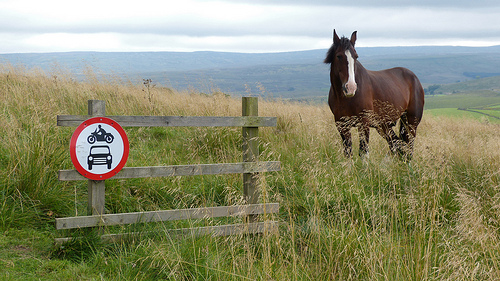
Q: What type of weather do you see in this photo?
A: It is cloudy.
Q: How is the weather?
A: It is cloudy.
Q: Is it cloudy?
A: Yes, it is cloudy.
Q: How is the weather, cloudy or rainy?
A: It is cloudy.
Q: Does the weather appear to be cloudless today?
A: No, it is cloudy.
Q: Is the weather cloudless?
A: No, it is cloudy.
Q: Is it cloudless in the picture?
A: No, it is cloudy.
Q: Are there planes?
A: No, there are no planes.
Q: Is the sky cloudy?
A: Yes, the sky is cloudy.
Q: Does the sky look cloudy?
A: Yes, the sky is cloudy.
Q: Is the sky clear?
A: No, the sky is cloudy.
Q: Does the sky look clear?
A: No, the sky is cloudy.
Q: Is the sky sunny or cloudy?
A: The sky is cloudy.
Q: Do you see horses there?
A: Yes, there is a horse.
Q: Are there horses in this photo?
A: Yes, there is a horse.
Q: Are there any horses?
A: Yes, there is a horse.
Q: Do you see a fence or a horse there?
A: Yes, there is a horse.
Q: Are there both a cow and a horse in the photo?
A: No, there is a horse but no cows.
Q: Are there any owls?
A: No, there are no owls.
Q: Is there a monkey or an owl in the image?
A: No, there are no owls or monkeys.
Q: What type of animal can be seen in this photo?
A: The animal is a horse.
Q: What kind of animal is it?
A: The animal is a horse.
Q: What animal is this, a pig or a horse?
A: This is a horse.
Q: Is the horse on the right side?
A: Yes, the horse is on the right of the image.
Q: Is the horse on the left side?
A: No, the horse is on the right of the image.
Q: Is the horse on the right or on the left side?
A: The horse is on the right of the image.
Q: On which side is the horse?
A: The horse is on the right of the image.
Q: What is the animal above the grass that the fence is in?
A: The animal is a horse.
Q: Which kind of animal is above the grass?
A: The animal is a horse.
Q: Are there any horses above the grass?
A: Yes, there is a horse above the grass.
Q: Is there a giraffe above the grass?
A: No, there is a horse above the grass.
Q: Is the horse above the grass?
A: Yes, the horse is above the grass.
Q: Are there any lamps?
A: No, there are no lamps.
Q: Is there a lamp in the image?
A: No, there are no lamps.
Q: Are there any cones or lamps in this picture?
A: No, there are no lamps or cones.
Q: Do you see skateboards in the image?
A: No, there are no skateboards.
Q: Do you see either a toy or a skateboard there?
A: No, there are no skateboards or toys.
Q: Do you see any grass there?
A: Yes, there is grass.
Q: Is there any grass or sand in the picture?
A: Yes, there is grass.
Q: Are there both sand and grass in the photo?
A: No, there is grass but no sand.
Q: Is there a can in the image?
A: No, there are no cans.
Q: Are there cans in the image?
A: No, there are no cans.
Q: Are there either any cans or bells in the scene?
A: No, there are no cans or bells.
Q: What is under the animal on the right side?
A: The grass is under the horse.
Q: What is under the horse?
A: The grass is under the horse.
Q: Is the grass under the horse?
A: Yes, the grass is under the horse.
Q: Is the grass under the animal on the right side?
A: Yes, the grass is under the horse.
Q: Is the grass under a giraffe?
A: No, the grass is under the horse.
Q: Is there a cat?
A: No, there are no cats.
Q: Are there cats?
A: No, there are no cats.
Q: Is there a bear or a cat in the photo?
A: No, there are no cats or bears.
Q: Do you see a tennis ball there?
A: No, there are no tennis balls.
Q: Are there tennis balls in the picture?
A: No, there are no tennis balls.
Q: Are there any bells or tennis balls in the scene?
A: No, there are no tennis balls or bells.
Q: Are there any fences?
A: Yes, there is a fence.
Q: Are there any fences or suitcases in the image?
A: Yes, there is a fence.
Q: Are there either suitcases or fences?
A: Yes, there is a fence.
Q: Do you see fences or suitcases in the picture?
A: Yes, there is a fence.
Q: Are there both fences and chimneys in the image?
A: No, there is a fence but no chimneys.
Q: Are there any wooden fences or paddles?
A: Yes, there is a wood fence.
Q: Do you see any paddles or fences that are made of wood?
A: Yes, the fence is made of wood.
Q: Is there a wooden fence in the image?
A: Yes, there is a wood fence.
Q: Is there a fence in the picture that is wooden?
A: Yes, there is a fence that is wooden.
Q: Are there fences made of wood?
A: Yes, there is a fence that is made of wood.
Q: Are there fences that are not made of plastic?
A: Yes, there is a fence that is made of wood.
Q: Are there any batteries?
A: No, there are no batteries.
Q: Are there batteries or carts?
A: No, there are no batteries or carts.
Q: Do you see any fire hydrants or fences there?
A: Yes, there is a fence.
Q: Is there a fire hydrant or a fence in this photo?
A: Yes, there is a fence.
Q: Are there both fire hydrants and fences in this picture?
A: No, there is a fence but no fire hydrants.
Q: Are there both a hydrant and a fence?
A: No, there is a fence but no fire hydrants.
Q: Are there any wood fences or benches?
A: Yes, there is a wood fence.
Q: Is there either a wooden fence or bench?
A: Yes, there is a wood fence.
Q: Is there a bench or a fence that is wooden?
A: Yes, the fence is wooden.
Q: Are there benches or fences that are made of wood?
A: Yes, the fence is made of wood.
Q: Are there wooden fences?
A: Yes, there is a wood fence.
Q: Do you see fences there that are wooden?
A: Yes, there is a fence that is wooden.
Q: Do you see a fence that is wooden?
A: Yes, there is a fence that is wooden.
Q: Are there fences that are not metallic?
A: Yes, there is a wooden fence.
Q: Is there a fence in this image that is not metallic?
A: Yes, there is a wooden fence.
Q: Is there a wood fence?
A: Yes, there is a fence that is made of wood.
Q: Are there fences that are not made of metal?
A: Yes, there is a fence that is made of wood.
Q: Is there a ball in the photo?
A: No, there are no balls.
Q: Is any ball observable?
A: No, there are no balls.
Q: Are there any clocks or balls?
A: No, there are no balls or clocks.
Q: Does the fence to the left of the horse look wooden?
A: Yes, the fence is wooden.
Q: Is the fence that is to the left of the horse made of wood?
A: Yes, the fence is made of wood.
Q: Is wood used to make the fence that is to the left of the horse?
A: Yes, the fence is made of wood.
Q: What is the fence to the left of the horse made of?
A: The fence is made of wood.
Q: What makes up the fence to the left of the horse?
A: The fence is made of wood.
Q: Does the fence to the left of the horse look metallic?
A: No, the fence is wooden.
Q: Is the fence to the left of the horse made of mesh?
A: No, the fence is made of wood.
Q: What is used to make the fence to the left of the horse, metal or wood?
A: The fence is made of wood.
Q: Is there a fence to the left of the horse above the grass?
A: Yes, there is a fence to the left of the horse.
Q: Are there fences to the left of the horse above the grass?
A: Yes, there is a fence to the left of the horse.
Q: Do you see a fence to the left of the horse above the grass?
A: Yes, there is a fence to the left of the horse.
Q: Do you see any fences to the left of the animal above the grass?
A: Yes, there is a fence to the left of the horse.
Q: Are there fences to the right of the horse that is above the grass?
A: No, the fence is to the left of the horse.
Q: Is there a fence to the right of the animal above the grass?
A: No, the fence is to the left of the horse.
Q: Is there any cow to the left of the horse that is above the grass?
A: No, there is a fence to the left of the horse.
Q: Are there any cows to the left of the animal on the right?
A: No, there is a fence to the left of the horse.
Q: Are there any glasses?
A: No, there are no glasses.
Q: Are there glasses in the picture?
A: No, there are no glasses.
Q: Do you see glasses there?
A: No, there are no glasses.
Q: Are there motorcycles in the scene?
A: Yes, there is a motorcycle.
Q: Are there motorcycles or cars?
A: Yes, there is a motorcycle.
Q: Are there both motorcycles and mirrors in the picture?
A: No, there is a motorcycle but no mirrors.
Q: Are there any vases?
A: No, there are no vases.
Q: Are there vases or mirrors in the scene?
A: No, there are no vases or mirrors.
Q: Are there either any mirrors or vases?
A: No, there are no vases or mirrors.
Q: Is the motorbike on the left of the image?
A: Yes, the motorbike is on the left of the image.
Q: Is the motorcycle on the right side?
A: No, the motorcycle is on the left of the image.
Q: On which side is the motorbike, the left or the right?
A: The motorbike is on the left of the image.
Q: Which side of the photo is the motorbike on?
A: The motorbike is on the left of the image.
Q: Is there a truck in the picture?
A: No, there are no trucks.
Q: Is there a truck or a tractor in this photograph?
A: No, there are no trucks or tractors.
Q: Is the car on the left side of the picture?
A: Yes, the car is on the left of the image.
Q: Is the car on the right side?
A: No, the car is on the left of the image.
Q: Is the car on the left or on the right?
A: The car is on the left of the image.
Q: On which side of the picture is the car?
A: The car is on the left of the image.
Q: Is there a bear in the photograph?
A: No, there are no bears.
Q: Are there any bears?
A: No, there are no bears.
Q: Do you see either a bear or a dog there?
A: No, there are no bears or dogs.